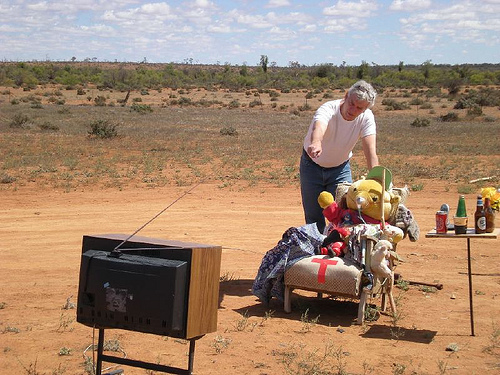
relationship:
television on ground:
[74, 232, 224, 341] [3, 61, 480, 369]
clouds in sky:
[0, 0, 500, 64] [3, 2, 484, 62]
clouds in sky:
[37, 10, 109, 42] [20, 4, 445, 64]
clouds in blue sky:
[0, 0, 500, 64] [1, 1, 498, 64]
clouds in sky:
[0, 0, 500, 64] [131, 9, 456, 64]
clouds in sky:
[0, 0, 500, 64] [9, 4, 499, 96]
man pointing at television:
[296, 81, 388, 217] [74, 232, 224, 341]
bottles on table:
[453, 193, 469, 235] [425, 219, 484, 346]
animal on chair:
[317, 169, 405, 259] [276, 172, 395, 324]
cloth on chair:
[248, 223, 318, 310] [283, 172, 408, 324]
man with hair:
[296, 77, 382, 226] [345, 79, 375, 108]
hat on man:
[372, 166, 399, 190] [297, 73, 381, 228]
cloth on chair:
[248, 223, 318, 310] [267, 172, 411, 327]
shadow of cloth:
[219, 268, 261, 310] [248, 223, 318, 310]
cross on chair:
[309, 255, 338, 285] [279, 222, 379, 324]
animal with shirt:
[317, 169, 405, 259] [277, 105, 467, 195]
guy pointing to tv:
[293, 75, 393, 246] [75, 227, 238, 308]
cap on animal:
[367, 162, 390, 187] [317, 169, 405, 259]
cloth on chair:
[253, 223, 318, 310] [274, 186, 403, 325]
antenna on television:
[113, 160, 226, 248] [74, 232, 224, 341]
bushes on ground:
[1, 64, 484, 179] [3, 61, 480, 369]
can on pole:
[434, 212, 449, 237] [465, 237, 476, 336]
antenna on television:
[111, 182, 199, 261] [74, 228, 221, 339]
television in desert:
[74, 228, 221, 339] [1, 59, 496, 372]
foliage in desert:
[2, 57, 494, 121] [1, 59, 496, 372]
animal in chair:
[320, 162, 415, 259] [266, 176, 406, 334]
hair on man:
[334, 76, 396, 119] [287, 58, 389, 238]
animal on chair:
[369, 238, 401, 320] [283, 172, 408, 324]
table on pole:
[424, 220, 499, 241] [461, 235, 477, 333]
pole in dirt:
[461, 235, 477, 333] [2, 175, 499, 372]